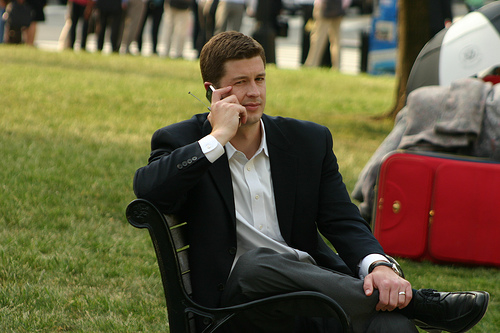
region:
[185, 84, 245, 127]
The cell phone being held by the man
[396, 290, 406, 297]
Wedding ring the man is wearing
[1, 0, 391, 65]
Line of people in the background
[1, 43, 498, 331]
Grass field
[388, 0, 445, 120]
Tree trunk in the background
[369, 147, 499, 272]
Red and black suitcase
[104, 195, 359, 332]
Bench the man is sitting on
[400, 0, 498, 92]
Black and white umbrella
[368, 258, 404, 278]
Watch on man's wrist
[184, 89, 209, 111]
The cell phone's antenna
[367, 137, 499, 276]
Red suitcase on grass.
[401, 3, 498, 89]
Grey and white umbrella.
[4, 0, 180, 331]
Grassy knoll next to busy street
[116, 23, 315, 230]
Man talking on cell phone.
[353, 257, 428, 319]
A golden wedding band.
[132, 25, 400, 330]
Man in black jacket.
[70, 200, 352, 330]
Black metal park bench.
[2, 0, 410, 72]
Pedestrians in the background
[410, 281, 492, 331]
Men's black dress shoes.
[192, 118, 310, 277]
Unbuttoned collar on white dress shirt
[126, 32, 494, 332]
a well dressed man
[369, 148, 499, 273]
a red piece of luggage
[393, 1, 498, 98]
a grey and white umbrella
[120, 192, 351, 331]
a black and grey chair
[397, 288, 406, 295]
a man's wedding ring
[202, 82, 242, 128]
a cell phone in a hand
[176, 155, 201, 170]
cufflink buttons on a sleeve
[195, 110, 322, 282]
a white button down shirt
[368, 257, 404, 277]
a man's wristwatch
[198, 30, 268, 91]
a man's short blond hair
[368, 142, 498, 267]
red and grey soft sided suitcase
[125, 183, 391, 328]
wood and metal black bench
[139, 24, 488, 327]
brown haired man sitting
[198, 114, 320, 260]
white button down shirt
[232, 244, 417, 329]
grey smooth dress pants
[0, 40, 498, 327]
green short well taken care of grass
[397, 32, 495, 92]
grey and white open umbrella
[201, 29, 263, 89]
short neatly styled brown hair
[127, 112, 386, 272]
black buttoned suit jacket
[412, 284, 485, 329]
shiny black lace up dress shoes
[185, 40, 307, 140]
The man is talking on the cell phone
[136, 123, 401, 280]
The man is wearing a black blazer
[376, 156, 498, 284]
The suitcase is red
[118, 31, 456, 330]
A man is sitting in a chair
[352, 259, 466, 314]
The man has on a wedding band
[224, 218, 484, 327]
The man has his legs folded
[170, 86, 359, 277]
The man has on a white shirt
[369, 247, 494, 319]
The man has on black shoes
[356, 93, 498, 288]
The suitcase is to the right of the man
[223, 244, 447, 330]
The pants are grey